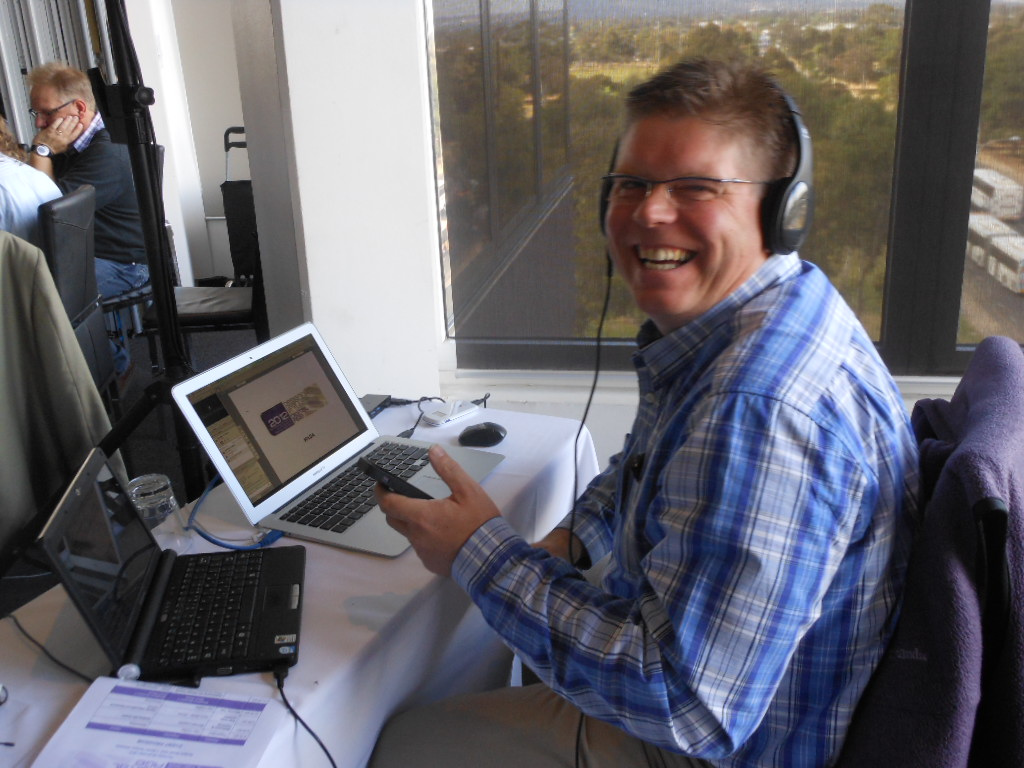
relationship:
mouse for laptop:
[460, 421, 510, 448] [168, 319, 503, 559]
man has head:
[25, 66, 153, 393] [30, 64, 98, 145]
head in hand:
[30, 64, 98, 145] [26, 114, 79, 154]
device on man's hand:
[358, 455, 441, 503] [371, 442, 499, 589]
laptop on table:
[168, 319, 503, 559] [12, 395, 600, 763]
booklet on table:
[34, 665, 294, 763] [12, 395, 600, 763]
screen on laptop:
[45, 453, 162, 661] [32, 448, 305, 682]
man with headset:
[377, 57, 933, 762] [586, 53, 811, 257]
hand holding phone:
[386, 446, 492, 580] [347, 453, 432, 503]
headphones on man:
[593, 68, 831, 259] [377, 57, 933, 762]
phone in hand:
[360, 457, 427, 503] [385, 442, 515, 572]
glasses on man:
[604, 166, 773, 203] [377, 57, 933, 762]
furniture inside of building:
[74, 303, 1016, 764] [128, 18, 1006, 395]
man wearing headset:
[354, 56, 920, 768] [744, 67, 814, 253]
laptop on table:
[30, 437, 309, 671] [12, 395, 600, 763]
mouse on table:
[458, 422, 507, 447] [12, 395, 600, 763]